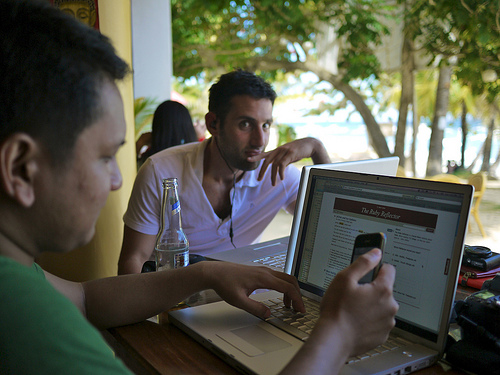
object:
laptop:
[171, 167, 474, 372]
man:
[0, 1, 399, 373]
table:
[110, 258, 498, 374]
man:
[118, 71, 331, 275]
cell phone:
[350, 230, 386, 285]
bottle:
[156, 177, 191, 310]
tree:
[174, 1, 393, 159]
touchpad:
[232, 323, 292, 353]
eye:
[239, 120, 250, 128]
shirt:
[1, 258, 133, 372]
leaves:
[338, 49, 382, 84]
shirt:
[124, 137, 301, 248]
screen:
[294, 165, 462, 335]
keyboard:
[251, 296, 396, 362]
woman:
[134, 99, 199, 165]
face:
[69, 81, 126, 257]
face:
[222, 94, 275, 173]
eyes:
[257, 118, 272, 131]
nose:
[250, 127, 267, 149]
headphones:
[208, 119, 243, 248]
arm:
[45, 261, 308, 326]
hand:
[319, 247, 400, 356]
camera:
[462, 243, 499, 272]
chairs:
[392, 167, 488, 239]